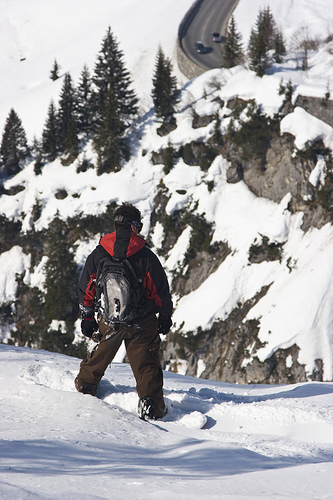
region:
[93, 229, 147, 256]
hood on a jacket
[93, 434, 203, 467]
shadow on the snow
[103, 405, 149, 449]
tracks in the snow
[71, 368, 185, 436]
feet deep in the snow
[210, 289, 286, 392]
mountainside covered in snow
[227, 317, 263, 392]
snow covered rock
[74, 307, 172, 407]
brown pants on a person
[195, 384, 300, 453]
white snow on the ground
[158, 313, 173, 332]
black glove on a person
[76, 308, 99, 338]
black glove on a person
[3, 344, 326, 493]
snowboard embedded in depression of snow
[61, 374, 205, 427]
snowboard covered in snow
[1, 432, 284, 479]
thin wavy shadows on snow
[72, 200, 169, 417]
silver backpack on skateboarder's back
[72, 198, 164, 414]
red and black jacket over brown pants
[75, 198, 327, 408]
thin and curved shadow of snowboarder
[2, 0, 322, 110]
elevated paved road with cars below mountain ridge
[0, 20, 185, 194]
evergreen trees on top of snow-covered mountain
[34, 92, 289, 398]
snowboarder looking at rocky mountain on other side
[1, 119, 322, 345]
rough edges of mountains between snow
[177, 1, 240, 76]
a mountain road below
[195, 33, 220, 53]
two cars on the mountain road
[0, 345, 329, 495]
white now on top of mountain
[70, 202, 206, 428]
man on snowboard on top of mountain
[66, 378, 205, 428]
a snowboard covered in snow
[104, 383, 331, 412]
man's shadow on the ground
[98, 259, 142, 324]
a black and silver backpack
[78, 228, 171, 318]
a red and black jacket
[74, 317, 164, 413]
the man's brown snow pants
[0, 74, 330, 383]
exposed rock surface of mountain below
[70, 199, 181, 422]
Man on a snowboard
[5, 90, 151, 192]
Evergreen trees on mountain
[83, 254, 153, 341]
Man wearing backpack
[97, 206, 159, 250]
Man wearing goggles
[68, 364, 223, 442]
snowboard on the snow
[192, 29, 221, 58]
Cars on the road in the distance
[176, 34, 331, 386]
Snow on the mountain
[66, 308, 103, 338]
Gloves on the snowboarder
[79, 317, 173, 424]
red ski pants worn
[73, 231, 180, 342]
Ski jacket on snowboarder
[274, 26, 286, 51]
green tree on mountain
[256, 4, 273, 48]
green tree on mountain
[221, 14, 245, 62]
green tree on mountain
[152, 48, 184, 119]
green tree on mountain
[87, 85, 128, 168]
green tree on mountain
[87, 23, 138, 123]
green tree on mountain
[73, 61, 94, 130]
green tree on mountain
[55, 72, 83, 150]
green tree on mountain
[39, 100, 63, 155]
green tree on mountain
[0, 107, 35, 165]
green tree on mountain